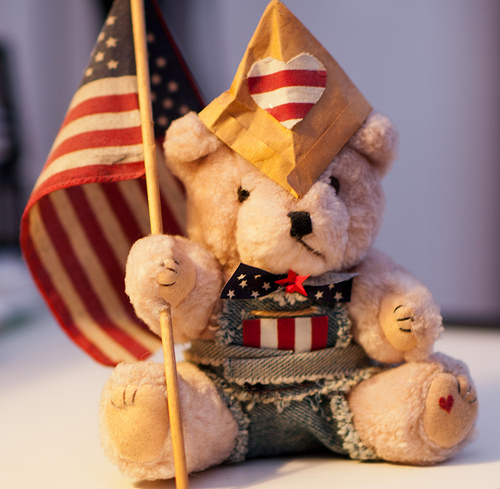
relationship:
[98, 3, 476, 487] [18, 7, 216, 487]
teddy bear holding flag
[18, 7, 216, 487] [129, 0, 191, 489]
flag has stick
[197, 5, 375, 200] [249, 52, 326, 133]
hat has striped heart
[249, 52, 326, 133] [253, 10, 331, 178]
striped heart in center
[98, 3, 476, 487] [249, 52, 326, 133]
teddy bear has striped heart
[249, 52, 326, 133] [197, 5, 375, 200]
striped heart on bottom of hat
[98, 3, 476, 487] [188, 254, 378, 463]
teddy bear wearing overalls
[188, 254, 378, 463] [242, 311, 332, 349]
overalls has stripe design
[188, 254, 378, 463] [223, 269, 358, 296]
overalls has stars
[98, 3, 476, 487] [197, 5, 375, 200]
teddy bear has hat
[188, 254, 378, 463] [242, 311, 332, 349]
overalls has striped heart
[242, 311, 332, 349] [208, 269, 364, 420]
stripes in front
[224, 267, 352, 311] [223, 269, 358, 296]
bowtie has stars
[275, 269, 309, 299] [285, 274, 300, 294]
star has sequin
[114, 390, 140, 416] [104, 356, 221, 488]
stitching are on paw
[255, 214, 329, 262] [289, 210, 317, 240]
stitching forming nose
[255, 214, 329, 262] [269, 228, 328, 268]
stitching forming mouth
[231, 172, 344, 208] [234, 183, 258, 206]
stitching forming eye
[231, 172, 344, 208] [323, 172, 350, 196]
stitching forming eye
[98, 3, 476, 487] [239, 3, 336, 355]
teddy bear has colors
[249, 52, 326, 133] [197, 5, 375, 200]
striped heart on hat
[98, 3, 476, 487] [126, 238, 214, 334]
teddy bear has hand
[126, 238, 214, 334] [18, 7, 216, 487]
hand holding flag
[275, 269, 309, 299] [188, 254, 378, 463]
star on overalls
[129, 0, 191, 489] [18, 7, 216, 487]
stick for flag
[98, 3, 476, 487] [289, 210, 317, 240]
teddy bear has nose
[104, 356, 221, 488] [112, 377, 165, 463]
paw has front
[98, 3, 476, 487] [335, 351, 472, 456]
teddy bear has leg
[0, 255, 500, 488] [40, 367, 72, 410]
table has a part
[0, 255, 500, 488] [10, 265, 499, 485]
table has a top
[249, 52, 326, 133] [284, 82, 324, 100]
striped heart has a part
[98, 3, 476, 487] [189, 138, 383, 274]
teddy bear has face